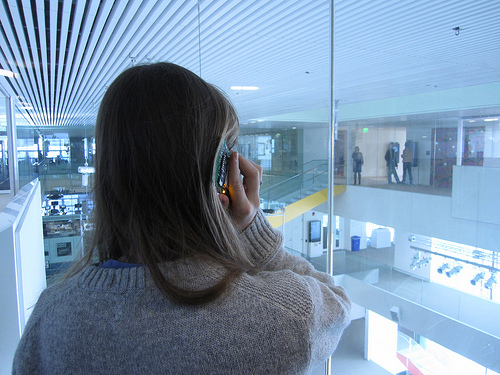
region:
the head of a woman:
[74, 65, 262, 277]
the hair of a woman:
[74, 54, 269, 269]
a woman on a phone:
[181, 120, 311, 231]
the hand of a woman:
[179, 116, 296, 243]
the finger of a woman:
[224, 139, 255, 191]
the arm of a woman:
[216, 173, 411, 336]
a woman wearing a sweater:
[33, 108, 374, 360]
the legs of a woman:
[340, 159, 387, 191]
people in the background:
[329, 92, 487, 188]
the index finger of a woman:
[220, 143, 259, 209]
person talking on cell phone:
[22, 35, 395, 372]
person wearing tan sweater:
[11, 160, 360, 372]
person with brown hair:
[51, 13, 281, 329]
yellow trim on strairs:
[252, 155, 347, 231]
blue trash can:
[341, 229, 362, 255]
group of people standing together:
[324, 125, 444, 202]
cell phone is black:
[203, 125, 260, 210]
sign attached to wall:
[292, 212, 330, 249]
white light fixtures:
[391, 240, 496, 316]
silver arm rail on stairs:
[259, 147, 344, 212]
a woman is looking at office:
[59, 20, 401, 342]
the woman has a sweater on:
[59, 23, 362, 373]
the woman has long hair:
[28, 29, 336, 371]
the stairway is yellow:
[259, 132, 373, 239]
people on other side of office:
[319, 111, 447, 217]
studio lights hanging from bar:
[396, 231, 493, 323]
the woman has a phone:
[86, 43, 317, 263]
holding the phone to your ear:
[79, 29, 319, 322]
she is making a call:
[79, 57, 298, 297]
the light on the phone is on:
[59, 17, 303, 314]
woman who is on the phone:
[7, 58, 347, 374]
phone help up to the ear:
[212, 147, 256, 207]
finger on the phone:
[226, 150, 247, 199]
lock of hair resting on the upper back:
[136, 255, 245, 318]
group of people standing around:
[340, 130, 428, 187]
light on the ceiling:
[229, 80, 263, 94]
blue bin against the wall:
[349, 230, 368, 252]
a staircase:
[250, 155, 339, 230]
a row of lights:
[408, 247, 498, 294]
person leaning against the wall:
[378, 140, 399, 186]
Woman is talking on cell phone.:
[0, 39, 357, 366]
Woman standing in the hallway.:
[330, 108, 376, 205]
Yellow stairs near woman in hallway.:
[195, 135, 386, 245]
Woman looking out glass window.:
[35, 30, 451, 357]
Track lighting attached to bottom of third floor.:
[390, 228, 498, 310]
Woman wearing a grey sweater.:
[29, 55, 363, 372]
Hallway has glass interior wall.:
[258, 100, 498, 218]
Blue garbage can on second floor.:
[337, 214, 381, 272]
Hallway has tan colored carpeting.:
[322, 226, 499, 336]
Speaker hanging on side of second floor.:
[346, 265, 494, 355]